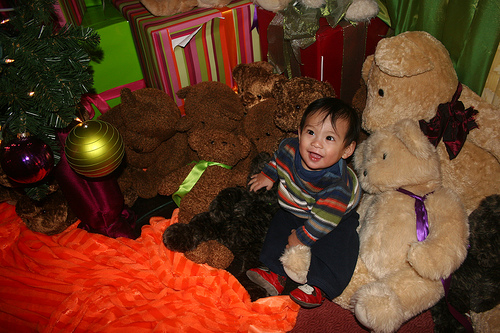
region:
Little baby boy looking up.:
[246, 99, 359, 311]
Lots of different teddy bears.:
[106, 43, 494, 322]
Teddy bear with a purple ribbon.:
[341, 132, 468, 327]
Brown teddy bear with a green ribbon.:
[158, 122, 251, 267]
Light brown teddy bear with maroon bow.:
[361, 34, 497, 209]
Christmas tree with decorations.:
[1, 12, 123, 232]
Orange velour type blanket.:
[3, 191, 305, 326]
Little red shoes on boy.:
[246, 95, 373, 314]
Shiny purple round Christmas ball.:
[2, 113, 58, 187]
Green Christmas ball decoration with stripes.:
[59, 109, 129, 181]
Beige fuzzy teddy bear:
[330, 117, 467, 331]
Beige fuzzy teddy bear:
[356, 30, 499, 218]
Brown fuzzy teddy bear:
[158, 124, 250, 274]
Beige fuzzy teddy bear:
[92, 83, 189, 203]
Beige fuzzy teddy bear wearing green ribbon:
[155, 125, 251, 270]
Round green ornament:
[61, 116, 126, 176]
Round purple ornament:
[1, 131, 55, 183]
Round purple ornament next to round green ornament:
[2, 119, 127, 186]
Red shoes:
[246, 260, 326, 307]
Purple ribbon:
[391, 184, 441, 241]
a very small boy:
[243, 93, 363, 304]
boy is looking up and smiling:
[295, 101, 362, 168]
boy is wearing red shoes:
[245, 264, 325, 306]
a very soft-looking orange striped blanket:
[1, 203, 298, 331]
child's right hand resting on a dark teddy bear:
[164, 149, 279, 281]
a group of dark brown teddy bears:
[106, 58, 307, 269]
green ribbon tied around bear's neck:
[171, 119, 247, 211]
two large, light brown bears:
[336, 29, 498, 331]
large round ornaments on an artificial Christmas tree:
[1, 3, 128, 201]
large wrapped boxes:
[50, 0, 387, 117]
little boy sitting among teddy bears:
[216, 90, 365, 309]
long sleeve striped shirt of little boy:
[262, 143, 348, 232]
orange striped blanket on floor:
[8, 200, 311, 332]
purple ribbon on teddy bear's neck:
[398, 183, 442, 242]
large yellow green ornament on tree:
[62, 115, 127, 173]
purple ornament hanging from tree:
[1, 133, 51, 183]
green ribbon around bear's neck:
[165, 159, 232, 200]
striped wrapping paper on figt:
[127, 1, 262, 96]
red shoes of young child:
[247, 264, 333, 307]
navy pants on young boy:
[268, 213, 367, 290]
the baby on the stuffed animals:
[248, 96, 360, 303]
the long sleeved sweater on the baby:
[256, 134, 355, 251]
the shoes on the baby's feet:
[245, 262, 323, 306]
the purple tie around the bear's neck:
[400, 178, 454, 293]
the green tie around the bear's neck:
[172, 157, 229, 207]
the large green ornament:
[63, 117, 123, 177]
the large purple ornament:
[7, 128, 53, 183]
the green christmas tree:
[1, 2, 93, 162]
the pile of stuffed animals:
[103, 33, 498, 318]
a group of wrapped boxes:
[53, 1, 398, 108]